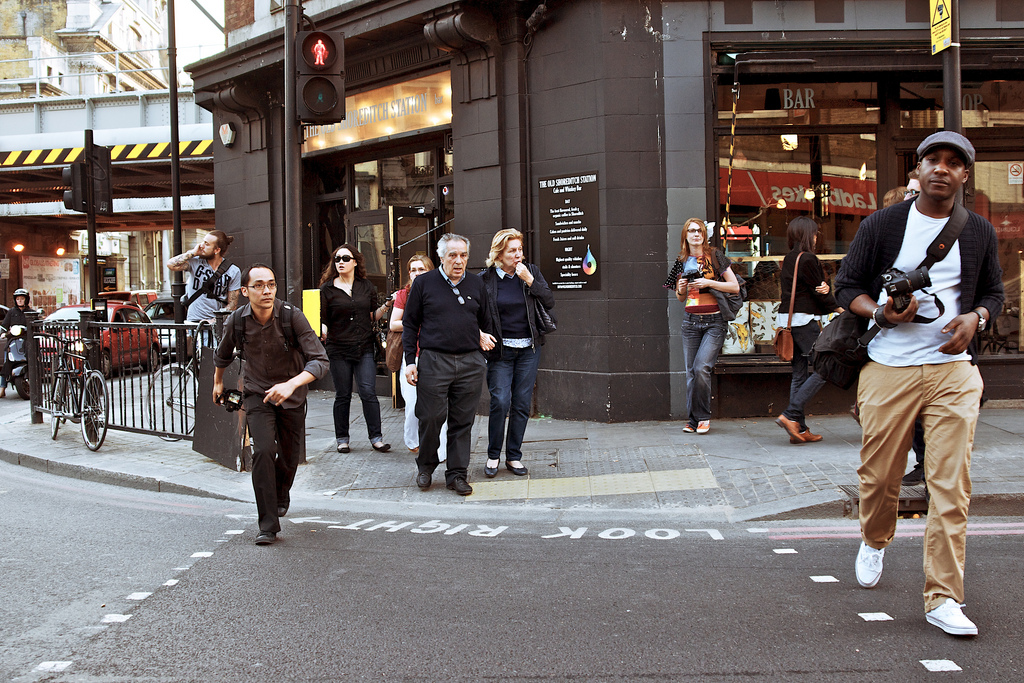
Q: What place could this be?
A: It is a street.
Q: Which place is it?
A: It is a street.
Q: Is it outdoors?
A: Yes, it is outdoors.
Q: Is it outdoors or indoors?
A: It is outdoors.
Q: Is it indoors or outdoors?
A: It is outdoors.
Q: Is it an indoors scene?
A: No, it is outdoors.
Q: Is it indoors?
A: No, it is outdoors.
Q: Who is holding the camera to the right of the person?
A: The man is holding the camera.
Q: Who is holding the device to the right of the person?
A: The man is holding the camera.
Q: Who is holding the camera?
A: The man is holding the camera.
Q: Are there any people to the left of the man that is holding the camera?
A: Yes, there is a person to the left of the man.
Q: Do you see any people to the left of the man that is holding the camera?
A: Yes, there is a person to the left of the man.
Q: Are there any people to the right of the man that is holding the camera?
A: No, the person is to the left of the man.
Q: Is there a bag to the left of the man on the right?
A: No, there is a person to the left of the man.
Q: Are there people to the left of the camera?
A: Yes, there is a person to the left of the camera.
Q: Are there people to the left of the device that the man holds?
A: Yes, there is a person to the left of the camera.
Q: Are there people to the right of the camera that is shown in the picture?
A: No, the person is to the left of the camera.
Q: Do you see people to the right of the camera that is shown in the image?
A: No, the person is to the left of the camera.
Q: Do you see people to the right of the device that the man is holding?
A: No, the person is to the left of the camera.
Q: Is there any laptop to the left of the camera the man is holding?
A: No, there is a person to the left of the camera.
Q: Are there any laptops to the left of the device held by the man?
A: No, there is a person to the left of the camera.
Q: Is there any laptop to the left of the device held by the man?
A: No, there is a person to the left of the camera.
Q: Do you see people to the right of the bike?
A: Yes, there is a person to the right of the bike.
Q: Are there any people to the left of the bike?
A: No, the person is to the right of the bike.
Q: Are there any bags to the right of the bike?
A: No, there is a person to the right of the bike.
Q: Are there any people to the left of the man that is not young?
A: Yes, there is a person to the left of the man.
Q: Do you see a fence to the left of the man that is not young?
A: No, there is a person to the left of the man.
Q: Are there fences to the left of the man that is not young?
A: No, there is a person to the left of the man.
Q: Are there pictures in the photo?
A: No, there are no pictures.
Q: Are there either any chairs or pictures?
A: No, there are no pictures or chairs.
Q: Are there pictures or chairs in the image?
A: No, there are no pictures or chairs.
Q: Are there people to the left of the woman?
A: Yes, there is a person to the left of the woman.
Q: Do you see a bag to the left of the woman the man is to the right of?
A: No, there is a person to the left of the woman.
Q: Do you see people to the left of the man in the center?
A: Yes, there is a person to the left of the man.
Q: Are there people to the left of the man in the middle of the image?
A: Yes, there is a person to the left of the man.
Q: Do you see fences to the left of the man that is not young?
A: No, there is a person to the left of the man.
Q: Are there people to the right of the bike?
A: Yes, there is a person to the right of the bike.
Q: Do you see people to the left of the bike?
A: No, the person is to the right of the bike.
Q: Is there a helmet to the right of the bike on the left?
A: No, there is a person to the right of the bike.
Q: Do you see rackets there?
A: No, there are no rackets.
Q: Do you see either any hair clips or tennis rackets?
A: No, there are no tennis rackets or hair clips.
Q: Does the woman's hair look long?
A: Yes, the hair is long.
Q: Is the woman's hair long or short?
A: The hair is long.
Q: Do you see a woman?
A: Yes, there is a woman.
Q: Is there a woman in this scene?
A: Yes, there is a woman.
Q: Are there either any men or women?
A: Yes, there is a woman.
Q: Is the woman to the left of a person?
A: Yes, the woman is to the left of a person.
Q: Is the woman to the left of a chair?
A: No, the woman is to the left of a person.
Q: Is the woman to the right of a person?
A: Yes, the woman is to the right of a person.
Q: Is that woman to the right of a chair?
A: No, the woman is to the right of a person.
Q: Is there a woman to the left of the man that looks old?
A: Yes, there is a woman to the left of the man.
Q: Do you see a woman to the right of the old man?
A: No, the woman is to the left of the man.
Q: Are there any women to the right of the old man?
A: No, the woman is to the left of the man.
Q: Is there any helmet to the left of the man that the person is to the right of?
A: No, there is a woman to the left of the man.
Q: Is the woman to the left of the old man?
A: Yes, the woman is to the left of the man.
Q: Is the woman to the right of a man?
A: No, the woman is to the left of a man.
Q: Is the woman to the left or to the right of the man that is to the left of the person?
A: The woman is to the left of the man.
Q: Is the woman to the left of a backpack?
A: No, the woman is to the left of a person.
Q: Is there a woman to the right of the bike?
A: Yes, there is a woman to the right of the bike.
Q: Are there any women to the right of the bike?
A: Yes, there is a woman to the right of the bike.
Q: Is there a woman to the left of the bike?
A: No, the woman is to the right of the bike.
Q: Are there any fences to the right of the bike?
A: No, there is a woman to the right of the bike.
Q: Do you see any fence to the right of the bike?
A: No, there is a woman to the right of the bike.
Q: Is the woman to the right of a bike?
A: Yes, the woman is to the right of a bike.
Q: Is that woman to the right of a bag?
A: No, the woman is to the right of a bike.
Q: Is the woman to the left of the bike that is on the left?
A: No, the woman is to the right of the bike.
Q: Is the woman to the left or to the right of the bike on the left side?
A: The woman is to the right of the bike.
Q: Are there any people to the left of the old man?
A: Yes, there is a person to the left of the man.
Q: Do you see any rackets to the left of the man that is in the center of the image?
A: No, there is a person to the left of the man.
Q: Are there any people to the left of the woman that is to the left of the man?
A: Yes, there is a person to the left of the woman.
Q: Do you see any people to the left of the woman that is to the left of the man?
A: Yes, there is a person to the left of the woman.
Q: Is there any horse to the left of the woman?
A: No, there is a person to the left of the woman.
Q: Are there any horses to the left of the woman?
A: No, there is a person to the left of the woman.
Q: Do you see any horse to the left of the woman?
A: No, there is a person to the left of the woman.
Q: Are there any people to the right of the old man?
A: Yes, there is a person to the right of the man.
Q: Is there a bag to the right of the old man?
A: No, there is a person to the right of the man.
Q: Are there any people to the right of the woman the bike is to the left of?
A: Yes, there is a person to the right of the woman.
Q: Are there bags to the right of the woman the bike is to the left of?
A: No, there is a person to the right of the woman.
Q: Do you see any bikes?
A: Yes, there is a bike.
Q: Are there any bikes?
A: Yes, there is a bike.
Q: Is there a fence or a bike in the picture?
A: Yes, there is a bike.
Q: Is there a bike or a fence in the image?
A: Yes, there is a bike.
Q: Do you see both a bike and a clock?
A: No, there is a bike but no clocks.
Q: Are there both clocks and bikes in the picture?
A: No, there is a bike but no clocks.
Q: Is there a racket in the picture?
A: No, there are no rackets.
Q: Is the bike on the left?
A: Yes, the bike is on the left of the image.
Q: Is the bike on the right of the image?
A: No, the bike is on the left of the image.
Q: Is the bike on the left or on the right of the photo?
A: The bike is on the left of the image.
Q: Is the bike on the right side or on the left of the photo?
A: The bike is on the left of the image.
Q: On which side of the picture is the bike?
A: The bike is on the left of the image.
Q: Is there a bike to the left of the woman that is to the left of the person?
A: Yes, there is a bike to the left of the woman.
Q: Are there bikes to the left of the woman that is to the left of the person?
A: Yes, there is a bike to the left of the woman.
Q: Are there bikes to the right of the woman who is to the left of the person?
A: No, the bike is to the left of the woman.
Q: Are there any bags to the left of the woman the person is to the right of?
A: No, there is a bike to the left of the woman.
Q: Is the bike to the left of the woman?
A: Yes, the bike is to the left of the woman.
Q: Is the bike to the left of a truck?
A: No, the bike is to the left of the woman.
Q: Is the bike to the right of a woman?
A: No, the bike is to the left of a woman.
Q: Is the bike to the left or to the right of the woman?
A: The bike is to the left of the woman.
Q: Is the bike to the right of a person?
A: No, the bike is to the left of a person.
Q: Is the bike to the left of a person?
A: Yes, the bike is to the left of a person.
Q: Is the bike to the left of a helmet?
A: No, the bike is to the left of a person.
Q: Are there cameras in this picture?
A: Yes, there is a camera.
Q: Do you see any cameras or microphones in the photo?
A: Yes, there is a camera.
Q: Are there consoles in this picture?
A: No, there are no consoles.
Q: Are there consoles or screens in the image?
A: No, there are no consoles or screens.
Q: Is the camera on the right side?
A: Yes, the camera is on the right of the image.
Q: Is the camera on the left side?
A: No, the camera is on the right of the image.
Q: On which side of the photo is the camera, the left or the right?
A: The camera is on the right of the image.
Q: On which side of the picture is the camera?
A: The camera is on the right of the image.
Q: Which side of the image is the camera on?
A: The camera is on the right of the image.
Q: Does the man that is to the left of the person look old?
A: Yes, the man is old.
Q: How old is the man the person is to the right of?
A: The man is old.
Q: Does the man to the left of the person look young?
A: No, the man is old.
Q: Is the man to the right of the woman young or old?
A: The man is old.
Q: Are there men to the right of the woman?
A: Yes, there is a man to the right of the woman.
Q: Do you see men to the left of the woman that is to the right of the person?
A: No, the man is to the right of the woman.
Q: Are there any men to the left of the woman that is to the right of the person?
A: No, the man is to the right of the woman.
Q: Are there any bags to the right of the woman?
A: No, there is a man to the right of the woman.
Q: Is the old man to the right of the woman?
A: Yes, the man is to the right of the woman.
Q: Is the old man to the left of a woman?
A: No, the man is to the right of a woman.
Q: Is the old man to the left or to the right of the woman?
A: The man is to the right of the woman.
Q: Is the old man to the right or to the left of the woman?
A: The man is to the right of the woman.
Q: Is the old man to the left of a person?
A: Yes, the man is to the left of a person.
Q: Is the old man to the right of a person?
A: No, the man is to the left of a person.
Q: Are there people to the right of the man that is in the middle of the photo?
A: Yes, there is a person to the right of the man.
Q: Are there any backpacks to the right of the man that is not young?
A: No, there is a person to the right of the man.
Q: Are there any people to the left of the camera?
A: Yes, there is a person to the left of the camera.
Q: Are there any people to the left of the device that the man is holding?
A: Yes, there is a person to the left of the camera.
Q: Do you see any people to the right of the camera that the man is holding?
A: No, the person is to the left of the camera.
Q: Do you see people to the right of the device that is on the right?
A: No, the person is to the left of the camera.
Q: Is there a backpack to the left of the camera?
A: No, there is a person to the left of the camera.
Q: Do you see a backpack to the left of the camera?
A: No, there is a person to the left of the camera.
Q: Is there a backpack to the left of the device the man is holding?
A: No, there is a person to the left of the camera.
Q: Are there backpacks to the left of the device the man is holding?
A: No, there is a person to the left of the camera.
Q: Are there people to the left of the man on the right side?
A: Yes, there is a person to the left of the man.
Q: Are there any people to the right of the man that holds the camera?
A: No, the person is to the left of the man.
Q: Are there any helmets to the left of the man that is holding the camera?
A: No, there is a person to the left of the man.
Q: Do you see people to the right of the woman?
A: Yes, there is a person to the right of the woman.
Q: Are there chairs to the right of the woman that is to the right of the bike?
A: No, there is a person to the right of the woman.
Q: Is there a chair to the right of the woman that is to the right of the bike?
A: No, there is a person to the right of the woman.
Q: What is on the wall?
A: The sign is on the wall.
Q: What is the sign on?
A: The sign is on the wall.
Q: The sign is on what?
A: The sign is on the wall.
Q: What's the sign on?
A: The sign is on the wall.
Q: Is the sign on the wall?
A: Yes, the sign is on the wall.